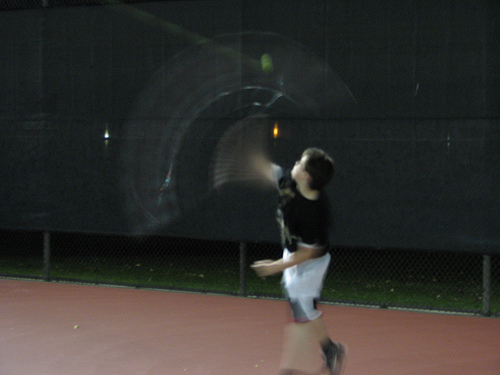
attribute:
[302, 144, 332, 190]
hair — dark brown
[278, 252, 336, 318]
shorts — black and white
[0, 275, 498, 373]
surface — hard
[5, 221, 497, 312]
fence — gray, chain link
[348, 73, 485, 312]
gate — metal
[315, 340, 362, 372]
shoes — black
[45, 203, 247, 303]
fence — Chain link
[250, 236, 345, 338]
shorts — white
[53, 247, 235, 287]
grass — short, green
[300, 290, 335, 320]
design — black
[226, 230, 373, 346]
shorts — white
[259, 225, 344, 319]
pants — white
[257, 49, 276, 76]
ball — green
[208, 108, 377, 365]
boy — skinny